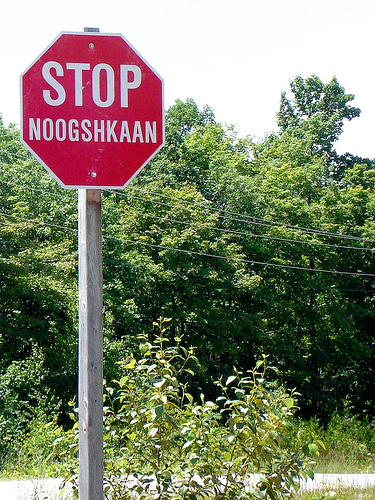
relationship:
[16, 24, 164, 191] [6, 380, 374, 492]
sign on side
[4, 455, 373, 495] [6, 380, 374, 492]
road has side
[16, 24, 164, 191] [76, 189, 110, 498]
sign attached to pole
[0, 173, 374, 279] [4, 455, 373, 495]
lines passing across road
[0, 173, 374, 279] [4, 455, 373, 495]
lines across road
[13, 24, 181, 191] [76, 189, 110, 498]
sign mounted on pole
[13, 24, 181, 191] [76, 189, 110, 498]
sign on pole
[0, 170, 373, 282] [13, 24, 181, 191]
wires behind sign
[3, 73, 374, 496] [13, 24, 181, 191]
trees behind sign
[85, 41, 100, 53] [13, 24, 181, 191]
screw on sign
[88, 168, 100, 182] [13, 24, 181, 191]
screw on sign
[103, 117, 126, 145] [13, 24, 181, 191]
letter on sign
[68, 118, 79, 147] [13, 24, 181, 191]
g on sign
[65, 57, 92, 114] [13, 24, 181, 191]
letter on sign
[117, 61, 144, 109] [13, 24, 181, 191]
letter on sign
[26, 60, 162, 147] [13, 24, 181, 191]
letters on sign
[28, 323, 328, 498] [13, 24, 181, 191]
greenery by sign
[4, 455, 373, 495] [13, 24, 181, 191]
road behind sign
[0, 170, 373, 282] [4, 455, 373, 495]
wires over road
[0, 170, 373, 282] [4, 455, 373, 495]
wires hanging over road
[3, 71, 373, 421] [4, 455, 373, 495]
trees behind road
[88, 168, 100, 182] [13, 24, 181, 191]
screw at sign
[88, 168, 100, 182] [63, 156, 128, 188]
screw at bottom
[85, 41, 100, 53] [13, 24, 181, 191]
screw at sign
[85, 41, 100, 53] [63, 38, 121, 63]
screw at top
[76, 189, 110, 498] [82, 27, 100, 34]
pole has tip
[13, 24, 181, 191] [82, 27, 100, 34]
sign mounted on tip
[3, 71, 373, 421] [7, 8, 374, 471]
trees in background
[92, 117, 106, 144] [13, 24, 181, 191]
letter on sign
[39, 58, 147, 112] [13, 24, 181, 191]
stop on sign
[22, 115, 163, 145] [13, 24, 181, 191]
word on sign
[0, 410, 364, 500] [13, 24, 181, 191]
weeds growing next to sign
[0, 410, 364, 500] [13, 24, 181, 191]
weeds next to sign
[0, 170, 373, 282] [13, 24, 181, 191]
wires above sign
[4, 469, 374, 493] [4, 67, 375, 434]
roadway along forest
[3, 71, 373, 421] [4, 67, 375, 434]
trees in forest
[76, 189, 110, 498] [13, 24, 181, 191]
pole supporting sign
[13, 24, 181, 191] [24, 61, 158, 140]
sign showing language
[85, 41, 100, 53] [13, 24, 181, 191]
screw fixing sign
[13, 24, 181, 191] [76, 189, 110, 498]
sign affixing sign to pole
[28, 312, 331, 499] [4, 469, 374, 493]
weeds along roadway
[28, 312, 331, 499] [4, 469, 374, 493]
weeds growing along roadway